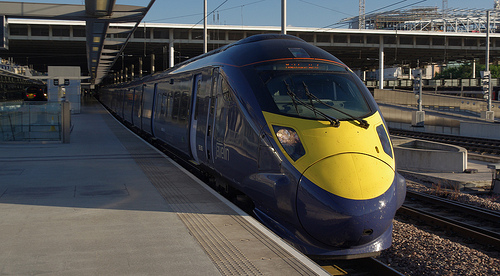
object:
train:
[96, 33, 410, 262]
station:
[1, 0, 500, 274]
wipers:
[283, 79, 369, 129]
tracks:
[383, 126, 497, 274]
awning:
[79, 0, 148, 96]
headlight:
[274, 126, 307, 159]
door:
[188, 71, 201, 166]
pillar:
[396, 138, 470, 173]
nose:
[298, 142, 403, 241]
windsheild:
[253, 58, 369, 122]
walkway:
[2, 91, 327, 276]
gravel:
[390, 218, 498, 276]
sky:
[0, 0, 500, 40]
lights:
[96, 88, 112, 104]